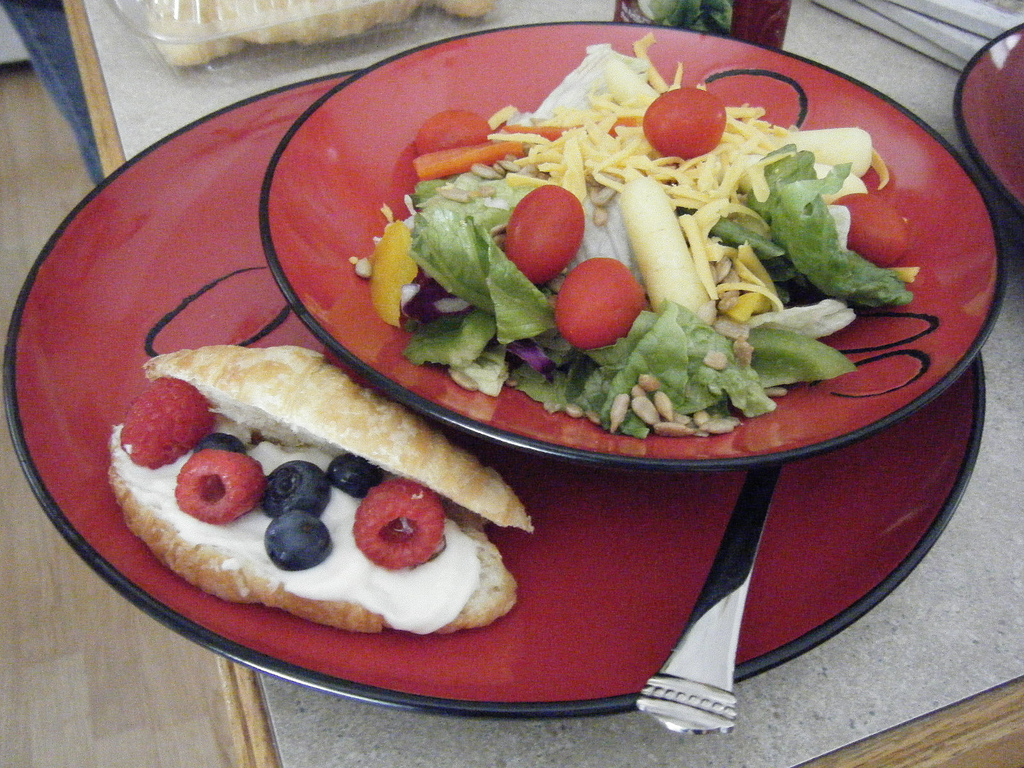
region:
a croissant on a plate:
[117, 356, 507, 633]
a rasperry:
[176, 452, 265, 513]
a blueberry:
[259, 461, 323, 506]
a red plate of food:
[264, 16, 992, 465]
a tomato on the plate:
[506, 187, 592, 286]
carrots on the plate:
[413, 119, 515, 171]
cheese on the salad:
[568, 83, 633, 150]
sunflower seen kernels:
[610, 392, 706, 431]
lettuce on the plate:
[765, 155, 896, 307]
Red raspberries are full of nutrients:
[114, 367, 219, 476]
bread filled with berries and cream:
[101, 333, 539, 635]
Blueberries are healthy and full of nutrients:
[256, 501, 333, 574]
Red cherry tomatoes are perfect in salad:
[639, 85, 728, 159]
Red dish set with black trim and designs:
[1, 17, 1005, 726]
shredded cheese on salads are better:
[478, 36, 924, 316]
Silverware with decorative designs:
[624, 452, 789, 744]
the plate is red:
[535, 539, 641, 617]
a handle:
[636, 650, 739, 750]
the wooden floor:
[35, 655, 185, 744]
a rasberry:
[357, 485, 433, 574]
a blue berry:
[259, 456, 336, 562]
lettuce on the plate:
[423, 229, 516, 293]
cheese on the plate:
[699, 163, 758, 202]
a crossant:
[234, 359, 317, 397]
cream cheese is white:
[385, 580, 478, 629]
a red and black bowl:
[261, 22, 1001, 463]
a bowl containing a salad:
[275, 25, 999, 474]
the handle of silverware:
[626, 468, 779, 745]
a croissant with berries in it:
[87, 342, 527, 627]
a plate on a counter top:
[26, 54, 1009, 697]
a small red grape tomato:
[645, 82, 732, 153]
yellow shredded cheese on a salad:
[536, 62, 787, 225]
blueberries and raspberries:
[111, 377, 450, 580]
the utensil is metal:
[593, 456, 799, 732]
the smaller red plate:
[256, 13, 997, 462]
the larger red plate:
[1, 67, 985, 713]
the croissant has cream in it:
[99, 345, 521, 628]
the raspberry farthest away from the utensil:
[114, 368, 206, 463]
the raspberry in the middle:
[169, 449, 265, 522]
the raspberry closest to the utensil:
[351, 471, 440, 574]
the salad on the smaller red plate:
[355, 32, 910, 448]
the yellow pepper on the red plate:
[362, 213, 430, 328]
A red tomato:
[553, 247, 639, 349]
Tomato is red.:
[553, 263, 639, 352]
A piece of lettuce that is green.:
[411, 203, 558, 355]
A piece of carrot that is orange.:
[404, 132, 528, 172]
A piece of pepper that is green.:
[755, 313, 839, 390]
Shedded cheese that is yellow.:
[524, 117, 641, 172]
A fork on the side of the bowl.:
[635, 481, 760, 734]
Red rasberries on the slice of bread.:
[353, 477, 434, 560]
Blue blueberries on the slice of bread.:
[265, 455, 336, 569]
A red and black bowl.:
[266, 23, 997, 469]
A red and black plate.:
[22, 35, 987, 725]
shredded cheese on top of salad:
[515, 28, 785, 251]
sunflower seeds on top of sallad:
[550, 306, 779, 453]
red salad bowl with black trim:
[236, 13, 1005, 462]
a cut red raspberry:
[354, 478, 450, 577]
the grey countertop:
[68, 18, 1021, 758]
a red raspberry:
[185, 454, 259, 516]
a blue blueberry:
[272, 511, 329, 569]